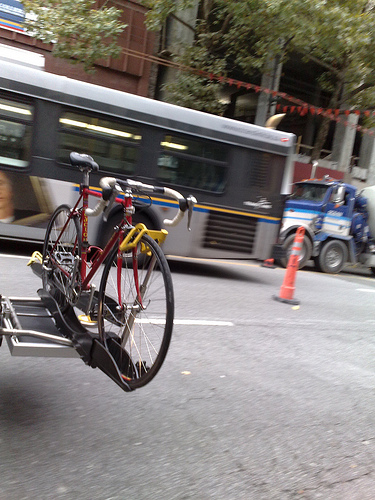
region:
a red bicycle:
[40, 150, 195, 392]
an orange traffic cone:
[273, 223, 307, 308]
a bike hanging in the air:
[40, 143, 195, 390]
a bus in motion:
[4, 56, 297, 261]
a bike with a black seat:
[29, 147, 197, 392]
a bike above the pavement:
[40, 146, 196, 420]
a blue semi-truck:
[283, 172, 374, 275]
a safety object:
[276, 223, 309, 309]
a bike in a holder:
[5, 150, 197, 392]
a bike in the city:
[30, 139, 196, 396]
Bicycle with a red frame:
[40, 151, 200, 389]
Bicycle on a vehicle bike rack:
[0, 151, 196, 391]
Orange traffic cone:
[272, 225, 306, 305]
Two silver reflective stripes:
[289, 240, 304, 256]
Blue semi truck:
[278, 174, 373, 277]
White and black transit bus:
[0, 56, 296, 276]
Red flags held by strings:
[190, 67, 373, 136]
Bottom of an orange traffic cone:
[260, 257, 276, 270]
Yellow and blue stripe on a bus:
[70, 181, 281, 227]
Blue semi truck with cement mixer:
[275, 173, 374, 278]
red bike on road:
[62, 180, 151, 335]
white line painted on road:
[169, 308, 239, 357]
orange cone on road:
[272, 208, 315, 307]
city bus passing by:
[29, 67, 264, 263]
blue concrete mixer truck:
[283, 168, 373, 269]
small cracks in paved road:
[295, 444, 369, 481]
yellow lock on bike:
[126, 223, 172, 254]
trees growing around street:
[168, 0, 372, 146]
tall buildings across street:
[112, 19, 373, 171]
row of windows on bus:
[36, 144, 280, 149]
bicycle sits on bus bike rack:
[1, 150, 197, 383]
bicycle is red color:
[74, 189, 92, 208]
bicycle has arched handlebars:
[90, 177, 196, 219]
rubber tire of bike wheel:
[157, 247, 175, 372]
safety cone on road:
[275, 224, 305, 304]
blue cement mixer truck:
[272, 174, 370, 268]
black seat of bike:
[66, 151, 103, 177]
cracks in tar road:
[263, 406, 371, 498]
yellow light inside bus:
[57, 117, 190, 142]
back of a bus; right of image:
[0, 57, 300, 254]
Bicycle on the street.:
[43, 137, 321, 425]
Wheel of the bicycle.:
[96, 208, 212, 405]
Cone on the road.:
[251, 203, 311, 321]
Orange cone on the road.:
[258, 220, 332, 313]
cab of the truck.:
[269, 145, 372, 243]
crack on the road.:
[190, 394, 291, 479]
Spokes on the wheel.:
[101, 219, 184, 370]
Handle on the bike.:
[96, 160, 243, 256]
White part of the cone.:
[252, 200, 313, 309]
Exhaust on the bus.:
[235, 100, 308, 141]